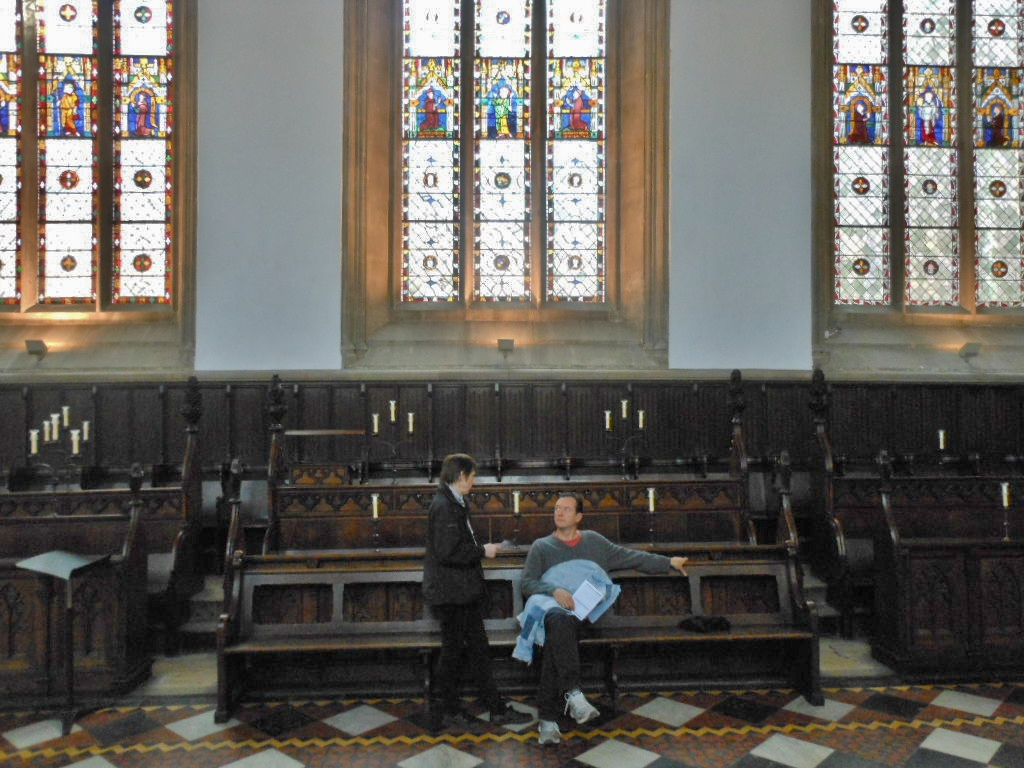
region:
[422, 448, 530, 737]
the man talking and standing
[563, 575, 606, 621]
the white paper in the mans hand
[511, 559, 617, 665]
the blue jacket in the hand of the man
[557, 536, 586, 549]
the red undershirt on the man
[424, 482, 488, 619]
the black jacket on the man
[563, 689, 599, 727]
the shoe on the mans foot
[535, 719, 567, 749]
the shoe is white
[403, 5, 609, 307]
the window is painted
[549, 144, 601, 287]
A window on a building.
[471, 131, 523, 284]
A window on a building.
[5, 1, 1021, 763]
people in interior of church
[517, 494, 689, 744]
seated man with outstretched arm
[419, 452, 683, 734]
standing person talking to seated amn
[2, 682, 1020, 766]
geometric designs on floor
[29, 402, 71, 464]
row of white candles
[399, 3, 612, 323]
row of stained glass windows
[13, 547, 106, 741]
tilted black music stand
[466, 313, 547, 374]
light reflection on window frame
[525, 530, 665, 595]
red shirt under gray sweater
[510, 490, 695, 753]
this man is sitting in the pew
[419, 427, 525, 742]
this man is standing next to the pew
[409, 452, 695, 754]
the two men are talking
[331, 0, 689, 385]
the center stained glass window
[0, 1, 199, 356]
the stain glass window on the left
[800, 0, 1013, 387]
the stained glass window on the right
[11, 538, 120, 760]
this is a music stand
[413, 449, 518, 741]
this man is wearing a suit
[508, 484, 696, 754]
this man is dressed casualy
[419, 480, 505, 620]
a black rain jacket without a hood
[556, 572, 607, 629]
a paper brochure in a man's hand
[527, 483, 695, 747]
a man sitting on a church pew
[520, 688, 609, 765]
a pair of grey athletic shoes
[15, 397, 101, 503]
a few candles on a candle holder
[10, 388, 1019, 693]
a few rows of wooden church pews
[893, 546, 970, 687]
a piece of beautifully decorative woodwork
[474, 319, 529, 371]
a light angled up at the window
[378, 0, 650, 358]
a series of stained glass windows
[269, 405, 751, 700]
people on the bench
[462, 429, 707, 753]
man sitting on bench